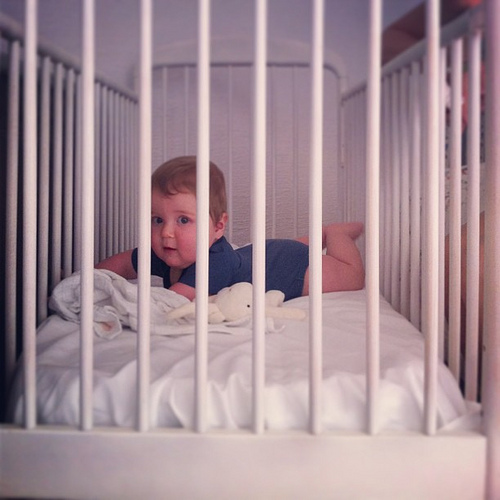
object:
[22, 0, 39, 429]
rail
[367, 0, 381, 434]
rail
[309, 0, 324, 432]
rail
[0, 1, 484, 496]
baby bed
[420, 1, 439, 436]
rail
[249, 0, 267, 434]
rail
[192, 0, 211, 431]
rail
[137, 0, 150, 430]
rail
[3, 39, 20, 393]
rail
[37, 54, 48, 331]
rail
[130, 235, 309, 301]
onesie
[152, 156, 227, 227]
hair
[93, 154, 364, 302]
baby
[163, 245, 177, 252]
mouth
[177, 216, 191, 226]
eye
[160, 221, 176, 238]
nose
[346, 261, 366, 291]
knee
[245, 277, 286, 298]
tummy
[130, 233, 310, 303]
romper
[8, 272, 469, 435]
crib sheet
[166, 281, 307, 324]
rabbit toy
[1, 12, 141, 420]
side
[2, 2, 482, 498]
side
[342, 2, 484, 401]
side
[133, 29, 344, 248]
side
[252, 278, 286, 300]
stomach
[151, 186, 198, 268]
face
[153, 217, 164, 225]
eye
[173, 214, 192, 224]
eye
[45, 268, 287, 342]
blanket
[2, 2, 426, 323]
wall